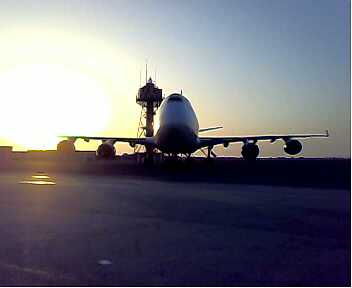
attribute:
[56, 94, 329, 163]
aircraft — ready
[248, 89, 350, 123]
side — bright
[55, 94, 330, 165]
plane — blocked, white, sit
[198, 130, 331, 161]
wing — sharp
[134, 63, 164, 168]
tower — back, at, air, pole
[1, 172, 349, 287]
grounds — darkened, glowing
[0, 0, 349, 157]
sky — blue, devoid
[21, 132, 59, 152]
sun — light, set, bright, up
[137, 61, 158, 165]
transformer — tall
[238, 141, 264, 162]
motor — four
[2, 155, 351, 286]
tarmac — dark